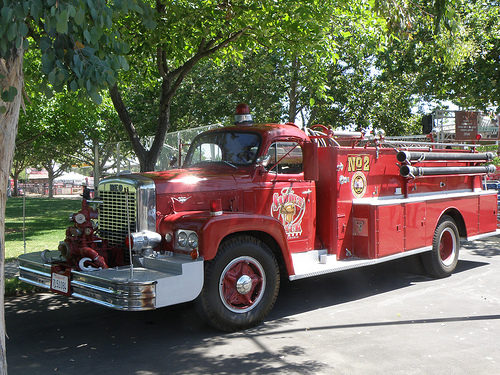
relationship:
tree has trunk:
[0, 3, 167, 338] [0, 32, 25, 343]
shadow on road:
[164, 300, 341, 373] [94, 225, 493, 373]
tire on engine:
[201, 240, 281, 330] [15, 120, 495, 332]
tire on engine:
[406, 214, 460, 278] [17, 104, 499, 333]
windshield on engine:
[183, 131, 262, 169] [17, 104, 499, 333]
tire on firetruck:
[193, 234, 281, 333] [12, 98, 497, 327]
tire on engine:
[414, 207, 464, 281] [17, 104, 499, 333]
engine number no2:
[17, 104, 499, 333] [343, 149, 375, 173]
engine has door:
[17, 104, 499, 333] [250, 120, 318, 267]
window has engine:
[261, 132, 310, 185] [17, 104, 499, 333]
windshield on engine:
[181, 126, 256, 171] [17, 104, 499, 333]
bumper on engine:
[17, 253, 157, 313] [17, 104, 499, 333]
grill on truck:
[88, 178, 148, 238] [27, 234, 205, 326]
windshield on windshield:
[183, 131, 262, 169] [183, 131, 262, 169]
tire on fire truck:
[201, 240, 281, 330] [188, 110, 433, 272]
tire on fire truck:
[406, 214, 460, 278] [188, 110, 433, 272]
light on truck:
[231, 102, 253, 123] [36, 101, 498, 316]